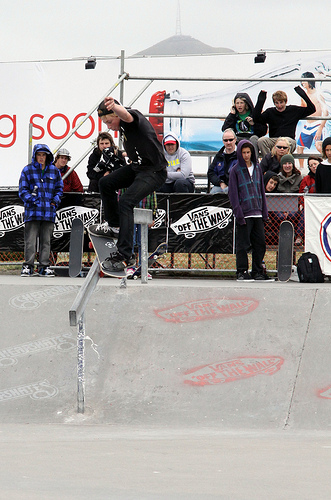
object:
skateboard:
[276, 219, 296, 281]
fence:
[0, 190, 331, 274]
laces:
[94, 219, 108, 233]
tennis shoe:
[87, 222, 118, 238]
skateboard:
[83, 226, 129, 277]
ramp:
[0, 283, 331, 433]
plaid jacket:
[17, 143, 65, 225]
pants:
[98, 164, 168, 260]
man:
[86, 97, 168, 273]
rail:
[67, 256, 99, 328]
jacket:
[227, 137, 268, 224]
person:
[205, 123, 237, 195]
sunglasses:
[222, 137, 235, 142]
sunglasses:
[274, 143, 288, 150]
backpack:
[296, 249, 324, 283]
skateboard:
[67, 219, 84, 279]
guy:
[227, 137, 276, 283]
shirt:
[123, 109, 169, 173]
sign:
[170, 205, 233, 239]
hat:
[96, 97, 131, 117]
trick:
[85, 95, 169, 281]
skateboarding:
[86, 220, 131, 284]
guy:
[17, 143, 65, 279]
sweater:
[163, 133, 194, 183]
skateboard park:
[0, 0, 331, 498]